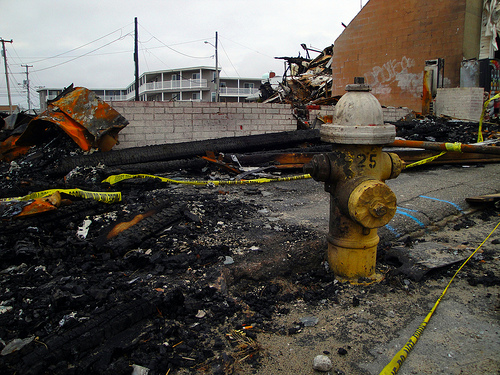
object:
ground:
[0, 123, 500, 363]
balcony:
[44, 77, 209, 101]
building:
[34, 64, 268, 113]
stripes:
[384, 223, 401, 239]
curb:
[376, 165, 500, 243]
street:
[1, 134, 500, 374]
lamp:
[203, 40, 215, 48]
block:
[433, 86, 486, 124]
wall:
[102, 98, 299, 150]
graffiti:
[362, 53, 452, 99]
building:
[330, 0, 483, 115]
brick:
[329, 0, 464, 115]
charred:
[393, 109, 500, 146]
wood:
[395, 149, 499, 165]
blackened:
[301, 140, 355, 239]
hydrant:
[301, 75, 408, 289]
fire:
[0, 79, 335, 375]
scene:
[0, 0, 498, 371]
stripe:
[395, 205, 427, 229]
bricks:
[397, 45, 409, 53]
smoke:
[458, 59, 480, 88]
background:
[0, 0, 372, 116]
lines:
[48, 48, 98, 68]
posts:
[0, 37, 14, 117]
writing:
[361, 54, 454, 107]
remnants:
[86, 115, 94, 119]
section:
[274, 279, 500, 375]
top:
[344, 76, 373, 93]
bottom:
[325, 233, 386, 286]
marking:
[418, 195, 466, 216]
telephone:
[0, 34, 35, 115]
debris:
[195, 144, 331, 182]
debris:
[247, 41, 334, 104]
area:
[0, 163, 500, 374]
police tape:
[376, 221, 498, 375]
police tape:
[0, 187, 123, 204]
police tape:
[99, 172, 312, 185]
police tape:
[405, 141, 463, 168]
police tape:
[477, 92, 500, 141]